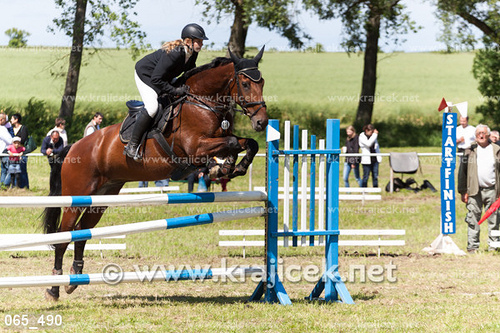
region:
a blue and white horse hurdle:
[0, 122, 356, 303]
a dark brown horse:
[47, 56, 268, 296]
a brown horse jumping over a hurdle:
[44, 52, 269, 300]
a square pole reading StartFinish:
[439, 108, 455, 235]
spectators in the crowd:
[0, 110, 385, 188]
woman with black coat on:
[128, 24, 208, 158]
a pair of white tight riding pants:
[132, 64, 157, 116]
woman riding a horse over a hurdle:
[46, 26, 268, 303]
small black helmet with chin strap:
[179, 24, 209, 53]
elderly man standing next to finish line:
[459, 125, 499, 257]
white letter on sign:
[443, 110, 452, 125]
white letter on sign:
[443, 123, 454, 137]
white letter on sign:
[440, 135, 455, 145]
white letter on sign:
[444, 145, 454, 159]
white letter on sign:
[444, 155, 452, 166]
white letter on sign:
[443, 165, 453, 176]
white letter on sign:
[443, 178, 450, 188]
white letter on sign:
[443, 187, 453, 202]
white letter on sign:
[443, 198, 452, 209]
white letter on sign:
[443, 210, 450, 220]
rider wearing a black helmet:
[178, 22, 209, 42]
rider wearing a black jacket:
[133, 43, 196, 98]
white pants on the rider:
[131, 68, 162, 116]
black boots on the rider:
[123, 105, 155, 160]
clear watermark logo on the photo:
[100, 260, 399, 285]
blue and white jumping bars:
[0, 190, 262, 290]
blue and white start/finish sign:
[439, 110, 459, 235]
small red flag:
[434, 95, 448, 114]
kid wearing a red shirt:
[5, 143, 27, 162]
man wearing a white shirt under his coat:
[474, 142, 496, 189]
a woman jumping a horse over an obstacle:
[40, 17, 270, 309]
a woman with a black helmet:
[179, 19, 207, 41]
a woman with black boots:
[120, 109, 158, 163]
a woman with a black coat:
[130, 40, 218, 93]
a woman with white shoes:
[130, 64, 173, 121]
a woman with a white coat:
[357, 128, 386, 163]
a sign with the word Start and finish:
[438, 112, 463, 239]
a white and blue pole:
[1, 190, 268, 210]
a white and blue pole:
[0, 204, 265, 251]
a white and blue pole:
[1, 264, 265, 289]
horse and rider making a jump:
[40, 21, 270, 299]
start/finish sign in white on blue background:
[417, 95, 467, 250]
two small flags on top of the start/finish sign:
[430, 95, 470, 116]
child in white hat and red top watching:
[0, 135, 25, 190]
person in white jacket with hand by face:
[357, 120, 379, 182]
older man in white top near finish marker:
[456, 120, 496, 250]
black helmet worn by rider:
[177, 20, 204, 50]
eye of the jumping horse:
[237, 75, 247, 90]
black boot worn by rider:
[120, 105, 150, 156]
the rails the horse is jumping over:
[0, 190, 265, 287]